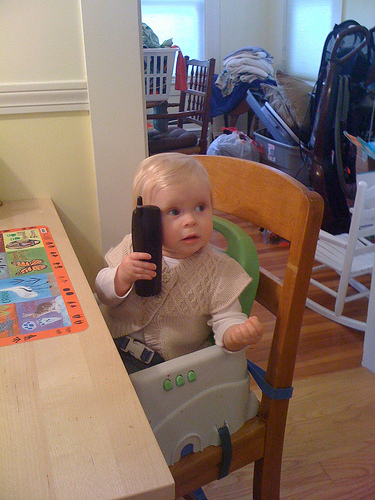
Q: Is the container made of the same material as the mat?
A: Yes, both the container and the mat are made of plastic.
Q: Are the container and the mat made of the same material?
A: Yes, both the container and the mat are made of plastic.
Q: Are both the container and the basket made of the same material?
A: Yes, both the container and the basket are made of plastic.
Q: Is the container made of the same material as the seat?
A: Yes, both the container and the seat are made of plastic.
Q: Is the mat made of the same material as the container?
A: Yes, both the mat and the container are made of plastic.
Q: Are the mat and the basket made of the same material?
A: Yes, both the mat and the basket are made of plastic.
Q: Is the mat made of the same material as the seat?
A: Yes, both the mat and the seat are made of plastic.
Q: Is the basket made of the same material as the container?
A: Yes, both the basket and the container are made of plastic.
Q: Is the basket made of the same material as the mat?
A: Yes, both the basket and the mat are made of plastic.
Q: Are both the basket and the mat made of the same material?
A: Yes, both the basket and the mat are made of plastic.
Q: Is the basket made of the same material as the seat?
A: Yes, both the basket and the seat are made of plastic.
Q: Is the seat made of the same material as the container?
A: Yes, both the seat and the container are made of plastic.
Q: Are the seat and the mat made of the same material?
A: Yes, both the seat and the mat are made of plastic.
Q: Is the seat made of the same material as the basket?
A: Yes, both the seat and the basket are made of plastic.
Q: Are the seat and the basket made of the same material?
A: Yes, both the seat and the basket are made of plastic.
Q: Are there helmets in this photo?
A: No, there are no helmets.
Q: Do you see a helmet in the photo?
A: No, there are no helmets.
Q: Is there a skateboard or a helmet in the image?
A: No, there are no helmets or skateboards.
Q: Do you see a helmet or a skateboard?
A: No, there are no helmets or skateboards.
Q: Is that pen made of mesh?
A: Yes, the pen is made of mesh.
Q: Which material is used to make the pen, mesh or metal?
A: The pen is made of mesh.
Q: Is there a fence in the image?
A: No, there are no fences.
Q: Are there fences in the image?
A: No, there are no fences.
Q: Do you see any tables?
A: Yes, there is a table.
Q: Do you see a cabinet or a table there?
A: Yes, there is a table.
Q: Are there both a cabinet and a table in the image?
A: No, there is a table but no cabinets.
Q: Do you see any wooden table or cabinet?
A: Yes, there is a wood table.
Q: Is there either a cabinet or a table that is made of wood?
A: Yes, the table is made of wood.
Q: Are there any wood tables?
A: Yes, there is a table that is made of wood.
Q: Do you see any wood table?
A: Yes, there is a table that is made of wood.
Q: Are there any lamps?
A: No, there are no lamps.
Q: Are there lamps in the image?
A: No, there are no lamps.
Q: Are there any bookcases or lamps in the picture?
A: No, there are no lamps or bookcases.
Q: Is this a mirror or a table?
A: This is a table.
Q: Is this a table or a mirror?
A: This is a table.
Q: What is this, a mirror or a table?
A: This is a table.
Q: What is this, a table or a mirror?
A: This is a table.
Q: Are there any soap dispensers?
A: No, there are no soap dispensers.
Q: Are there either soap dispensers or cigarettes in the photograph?
A: No, there are no soap dispensers or cigarettes.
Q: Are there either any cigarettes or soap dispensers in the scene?
A: No, there are no soap dispensers or cigarettes.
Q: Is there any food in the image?
A: No, there is no food.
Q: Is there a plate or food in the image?
A: No, there are no food or plates.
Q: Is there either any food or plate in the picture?
A: No, there are no food or plates.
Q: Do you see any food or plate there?
A: No, there are no food or plates.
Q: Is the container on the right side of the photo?
A: Yes, the container is on the right of the image.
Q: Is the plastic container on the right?
A: Yes, the container is on the right of the image.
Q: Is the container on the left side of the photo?
A: No, the container is on the right of the image.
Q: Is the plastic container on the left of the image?
A: No, the container is on the right of the image.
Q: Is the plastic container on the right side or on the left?
A: The container is on the right of the image.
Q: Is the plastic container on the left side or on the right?
A: The container is on the right of the image.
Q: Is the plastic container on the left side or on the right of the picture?
A: The container is on the right of the image.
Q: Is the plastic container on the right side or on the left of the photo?
A: The container is on the right of the image.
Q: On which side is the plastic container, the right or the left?
A: The container is on the right of the image.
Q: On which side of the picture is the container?
A: The container is on the right of the image.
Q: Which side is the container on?
A: The container is on the right of the image.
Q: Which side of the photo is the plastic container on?
A: The container is on the right of the image.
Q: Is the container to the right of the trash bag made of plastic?
A: Yes, the container is made of plastic.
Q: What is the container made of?
A: The container is made of plastic.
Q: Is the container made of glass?
A: No, the container is made of plastic.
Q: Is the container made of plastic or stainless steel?
A: The container is made of plastic.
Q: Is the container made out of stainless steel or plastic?
A: The container is made of plastic.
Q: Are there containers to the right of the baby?
A: Yes, there is a container to the right of the baby.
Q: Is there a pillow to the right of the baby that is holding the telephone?
A: No, there is a container to the right of the baby.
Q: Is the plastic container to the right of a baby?
A: Yes, the container is to the right of a baby.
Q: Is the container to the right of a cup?
A: No, the container is to the right of a baby.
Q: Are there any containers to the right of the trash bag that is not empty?
A: Yes, there is a container to the right of the trash bag.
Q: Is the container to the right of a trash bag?
A: Yes, the container is to the right of a trash bag.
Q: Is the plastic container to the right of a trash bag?
A: Yes, the container is to the right of a trash bag.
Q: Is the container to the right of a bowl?
A: No, the container is to the right of a trash bag.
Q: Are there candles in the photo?
A: No, there are no candles.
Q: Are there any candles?
A: No, there are no candles.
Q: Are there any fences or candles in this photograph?
A: No, there are no candles or fences.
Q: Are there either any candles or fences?
A: No, there are no candles or fences.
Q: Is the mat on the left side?
A: Yes, the mat is on the left of the image.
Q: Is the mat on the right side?
A: No, the mat is on the left of the image.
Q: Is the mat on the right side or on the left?
A: The mat is on the left of the image.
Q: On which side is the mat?
A: The mat is on the left of the image.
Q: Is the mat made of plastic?
A: Yes, the mat is made of plastic.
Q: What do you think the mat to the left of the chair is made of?
A: The mat is made of plastic.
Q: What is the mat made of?
A: The mat is made of plastic.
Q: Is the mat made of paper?
A: No, the mat is made of plastic.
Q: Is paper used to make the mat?
A: No, the mat is made of plastic.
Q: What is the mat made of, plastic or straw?
A: The mat is made of plastic.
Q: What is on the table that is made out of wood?
A: The mat is on the table.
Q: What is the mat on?
A: The mat is on the table.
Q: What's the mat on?
A: The mat is on the table.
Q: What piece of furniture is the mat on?
A: The mat is on the table.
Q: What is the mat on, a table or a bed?
A: The mat is on a table.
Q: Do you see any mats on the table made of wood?
A: Yes, there is a mat on the table.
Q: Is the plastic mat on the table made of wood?
A: Yes, the mat is on the table.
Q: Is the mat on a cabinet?
A: No, the mat is on the table.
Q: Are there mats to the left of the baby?
A: Yes, there is a mat to the left of the baby.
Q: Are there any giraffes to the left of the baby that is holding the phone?
A: No, there is a mat to the left of the baby.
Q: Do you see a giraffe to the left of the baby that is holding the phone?
A: No, there is a mat to the left of the baby.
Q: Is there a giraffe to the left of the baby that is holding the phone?
A: No, there is a mat to the left of the baby.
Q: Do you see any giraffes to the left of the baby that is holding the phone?
A: No, there is a mat to the left of the baby.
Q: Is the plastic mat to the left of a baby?
A: Yes, the mat is to the left of a baby.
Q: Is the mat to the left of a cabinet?
A: No, the mat is to the left of a baby.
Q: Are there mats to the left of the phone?
A: Yes, there is a mat to the left of the phone.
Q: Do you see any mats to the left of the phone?
A: Yes, there is a mat to the left of the phone.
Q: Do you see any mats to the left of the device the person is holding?
A: Yes, there is a mat to the left of the phone.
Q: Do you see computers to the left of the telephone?
A: No, there is a mat to the left of the telephone.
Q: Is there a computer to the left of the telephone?
A: No, there is a mat to the left of the telephone.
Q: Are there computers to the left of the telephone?
A: No, there is a mat to the left of the telephone.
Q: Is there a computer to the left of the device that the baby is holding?
A: No, there is a mat to the left of the telephone.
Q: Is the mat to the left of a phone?
A: Yes, the mat is to the left of a phone.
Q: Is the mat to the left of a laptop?
A: No, the mat is to the left of a phone.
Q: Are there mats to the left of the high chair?
A: Yes, there is a mat to the left of the chair.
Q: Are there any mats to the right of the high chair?
A: No, the mat is to the left of the chair.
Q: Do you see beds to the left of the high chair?
A: No, there is a mat to the left of the chair.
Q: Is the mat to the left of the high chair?
A: Yes, the mat is to the left of the chair.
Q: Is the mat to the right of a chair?
A: No, the mat is to the left of a chair.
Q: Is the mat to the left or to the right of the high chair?
A: The mat is to the left of the chair.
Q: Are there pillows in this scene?
A: No, there are no pillows.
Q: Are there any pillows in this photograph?
A: No, there are no pillows.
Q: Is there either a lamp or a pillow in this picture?
A: No, there are no pillows or lamps.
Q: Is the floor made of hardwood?
A: Yes, the floor is made of hardwood.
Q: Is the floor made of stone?
A: No, the floor is made of hardwood.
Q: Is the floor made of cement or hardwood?
A: The floor is made of hardwood.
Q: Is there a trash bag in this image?
A: Yes, there is a trash bag.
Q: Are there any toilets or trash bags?
A: Yes, there is a trash bag.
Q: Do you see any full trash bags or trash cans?
A: Yes, there is a full trash bag.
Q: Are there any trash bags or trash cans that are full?
A: Yes, the trash bag is full.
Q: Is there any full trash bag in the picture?
A: Yes, there is a full trash bag.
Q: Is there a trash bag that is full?
A: Yes, there is a trash bag that is full.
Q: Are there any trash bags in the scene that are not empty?
A: Yes, there is an full trash bag.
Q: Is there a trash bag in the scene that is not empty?
A: Yes, there is an full trash bag.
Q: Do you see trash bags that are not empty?
A: Yes, there is an full trash bag.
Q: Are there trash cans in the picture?
A: No, there are no trash cans.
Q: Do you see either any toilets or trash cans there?
A: No, there are no trash cans or toilets.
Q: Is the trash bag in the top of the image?
A: Yes, the trash bag is in the top of the image.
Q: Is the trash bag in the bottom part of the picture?
A: No, the trash bag is in the top of the image.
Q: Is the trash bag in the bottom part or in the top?
A: The trash bag is in the top of the image.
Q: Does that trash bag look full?
A: Yes, the trash bag is full.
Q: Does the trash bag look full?
A: Yes, the trash bag is full.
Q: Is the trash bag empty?
A: No, the trash bag is full.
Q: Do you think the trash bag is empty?
A: No, the trash bag is full.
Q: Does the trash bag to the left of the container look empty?
A: No, the trash bag is full.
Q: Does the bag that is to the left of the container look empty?
A: No, the trash bag is full.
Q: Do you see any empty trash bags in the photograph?
A: No, there is a trash bag but it is full.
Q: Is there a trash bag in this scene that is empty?
A: No, there is a trash bag but it is full.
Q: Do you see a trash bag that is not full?
A: No, there is a trash bag but it is full.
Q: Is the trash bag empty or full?
A: The trash bag is full.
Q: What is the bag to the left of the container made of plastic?
A: The bag is a trash bag.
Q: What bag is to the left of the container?
A: The bag is a trash bag.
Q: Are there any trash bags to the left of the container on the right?
A: Yes, there is a trash bag to the left of the container.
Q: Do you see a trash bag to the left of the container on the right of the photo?
A: Yes, there is a trash bag to the left of the container.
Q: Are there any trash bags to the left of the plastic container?
A: Yes, there is a trash bag to the left of the container.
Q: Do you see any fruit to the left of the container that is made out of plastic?
A: No, there is a trash bag to the left of the container.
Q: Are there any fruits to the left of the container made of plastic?
A: No, there is a trash bag to the left of the container.